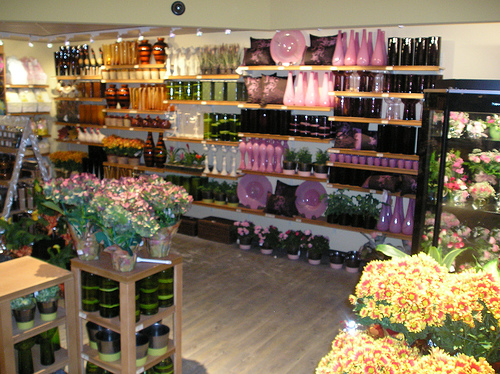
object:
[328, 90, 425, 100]
shelf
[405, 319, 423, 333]
flower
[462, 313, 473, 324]
flower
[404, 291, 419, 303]
flower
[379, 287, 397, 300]
flower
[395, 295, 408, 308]
flower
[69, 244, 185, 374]
table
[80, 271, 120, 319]
jars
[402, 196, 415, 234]
lavender vase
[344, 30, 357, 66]
lavender vase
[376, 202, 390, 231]
lavender vase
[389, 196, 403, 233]
lavender vase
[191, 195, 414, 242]
shelf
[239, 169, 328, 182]
shelf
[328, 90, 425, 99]
shelf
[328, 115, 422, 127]
shelf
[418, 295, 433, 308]
flower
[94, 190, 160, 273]
plant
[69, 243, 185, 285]
shelf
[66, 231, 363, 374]
floor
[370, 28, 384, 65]
vase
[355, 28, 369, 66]
vase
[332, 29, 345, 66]
vase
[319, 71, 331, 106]
vase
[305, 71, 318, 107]
vase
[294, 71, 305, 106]
vase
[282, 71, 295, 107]
vase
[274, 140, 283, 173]
vase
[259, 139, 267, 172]
vase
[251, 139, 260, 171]
vase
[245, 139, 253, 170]
vase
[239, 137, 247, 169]
vase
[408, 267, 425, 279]
flowers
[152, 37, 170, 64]
vase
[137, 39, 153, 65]
vase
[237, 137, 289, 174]
glassware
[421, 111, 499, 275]
flowers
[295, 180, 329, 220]
plate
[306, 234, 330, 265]
flower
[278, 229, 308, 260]
flower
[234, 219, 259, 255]
flower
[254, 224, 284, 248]
flower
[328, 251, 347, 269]
flower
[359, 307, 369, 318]
flowers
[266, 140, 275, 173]
vase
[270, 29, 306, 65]
pink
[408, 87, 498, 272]
case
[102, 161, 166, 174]
shelves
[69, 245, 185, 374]
shelves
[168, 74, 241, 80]
shelf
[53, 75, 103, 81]
shelf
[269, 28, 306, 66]
plate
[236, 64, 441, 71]
shelf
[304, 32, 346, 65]
pillow